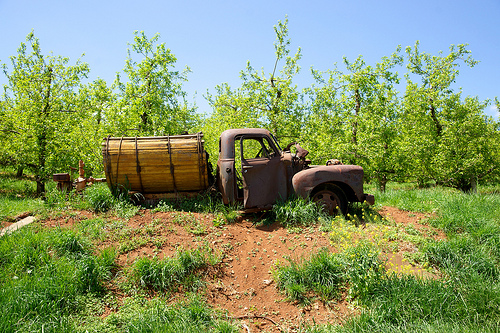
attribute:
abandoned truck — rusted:
[101, 124, 374, 218]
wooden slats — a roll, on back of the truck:
[101, 132, 207, 196]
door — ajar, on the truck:
[236, 131, 266, 210]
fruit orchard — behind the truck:
[8, 18, 484, 172]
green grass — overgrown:
[9, 180, 102, 330]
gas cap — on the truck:
[223, 163, 232, 173]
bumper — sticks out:
[364, 186, 375, 206]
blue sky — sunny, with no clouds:
[5, 2, 349, 82]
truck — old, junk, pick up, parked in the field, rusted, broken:
[96, 123, 379, 219]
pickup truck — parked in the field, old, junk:
[92, 126, 375, 216]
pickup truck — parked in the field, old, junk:
[101, 126, 376, 223]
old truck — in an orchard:
[97, 127, 376, 221]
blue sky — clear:
[3, 2, 443, 88]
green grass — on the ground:
[8, 220, 183, 328]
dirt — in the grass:
[222, 219, 285, 330]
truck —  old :
[101, 131, 390, 220]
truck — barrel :
[84, 133, 369, 213]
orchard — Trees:
[19, 40, 468, 130]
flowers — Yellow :
[325, 210, 427, 272]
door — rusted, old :
[218, 131, 277, 218]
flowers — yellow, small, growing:
[321, 220, 405, 250]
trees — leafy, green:
[4, 41, 484, 141]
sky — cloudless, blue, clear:
[11, 6, 484, 45]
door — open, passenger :
[218, 121, 289, 213]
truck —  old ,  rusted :
[103, 134, 363, 214]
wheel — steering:
[252, 139, 274, 166]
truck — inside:
[101, 133, 369, 209]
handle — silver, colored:
[244, 161, 254, 181]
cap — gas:
[224, 169, 232, 175]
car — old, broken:
[94, 135, 381, 216]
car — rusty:
[100, 127, 406, 221]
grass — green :
[22, 222, 471, 327]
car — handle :
[92, 130, 372, 215]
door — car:
[238, 140, 273, 209]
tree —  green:
[408, 61, 485, 180]